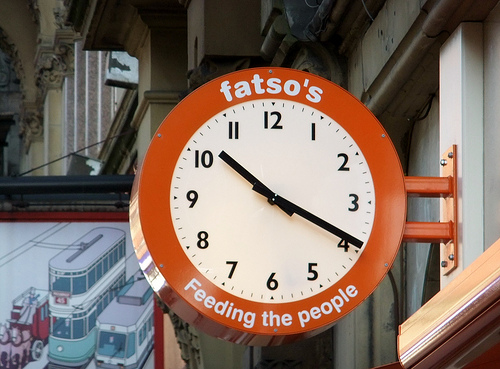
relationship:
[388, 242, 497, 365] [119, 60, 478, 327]
ledge by clock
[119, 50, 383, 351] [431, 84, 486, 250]
clock attached to wall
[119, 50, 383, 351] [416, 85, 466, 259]
clock attached to wall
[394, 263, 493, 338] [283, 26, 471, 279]
side trim on building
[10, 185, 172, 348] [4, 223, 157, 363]
picture of automobile transportation